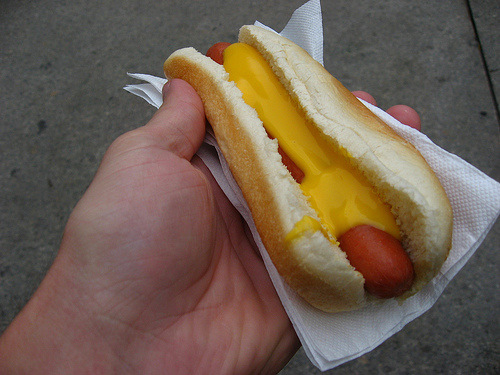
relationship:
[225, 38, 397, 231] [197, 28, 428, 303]
mustard on hot dog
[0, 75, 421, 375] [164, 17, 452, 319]
hand in bun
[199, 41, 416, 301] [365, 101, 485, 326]
hot dog in napkin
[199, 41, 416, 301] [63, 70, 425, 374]
hot dog in hand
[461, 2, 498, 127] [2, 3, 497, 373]
line in ground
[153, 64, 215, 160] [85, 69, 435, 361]
thumb in hand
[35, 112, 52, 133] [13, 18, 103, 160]
spot in ground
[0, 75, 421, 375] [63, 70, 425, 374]
hand in hand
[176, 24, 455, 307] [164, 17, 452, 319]
weiner in bun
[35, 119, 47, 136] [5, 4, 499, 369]
spot in counter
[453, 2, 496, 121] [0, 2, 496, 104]
streak in counter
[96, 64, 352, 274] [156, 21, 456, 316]
hand holding a hot dog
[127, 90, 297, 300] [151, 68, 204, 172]
hand has thumb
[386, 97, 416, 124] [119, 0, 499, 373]
finger behind napkin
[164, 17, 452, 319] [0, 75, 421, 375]
bun with hand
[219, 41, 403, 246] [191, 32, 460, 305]
mustard on hot dog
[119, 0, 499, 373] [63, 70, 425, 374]
napkin over hand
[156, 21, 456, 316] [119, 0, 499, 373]
hot dog over napkin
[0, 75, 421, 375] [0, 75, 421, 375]
hand holding hand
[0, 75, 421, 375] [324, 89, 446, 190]
hand in bun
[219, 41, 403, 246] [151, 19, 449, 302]
mustard on hotdog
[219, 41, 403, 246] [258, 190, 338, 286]
mustard over bun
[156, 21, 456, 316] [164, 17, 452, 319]
hot dog on a bun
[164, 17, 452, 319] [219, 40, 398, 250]
bun covered in sauce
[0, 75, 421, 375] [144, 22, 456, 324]
hand on a bun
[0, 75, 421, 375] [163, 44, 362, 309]
hand on a bun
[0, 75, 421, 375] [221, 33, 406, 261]
hand smothered in cheese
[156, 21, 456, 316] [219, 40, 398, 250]
hot dog smothered in sauce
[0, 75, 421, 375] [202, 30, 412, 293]
hand hold hotdog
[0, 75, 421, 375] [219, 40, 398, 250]
hand in sauce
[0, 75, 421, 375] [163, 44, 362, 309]
hand on bun